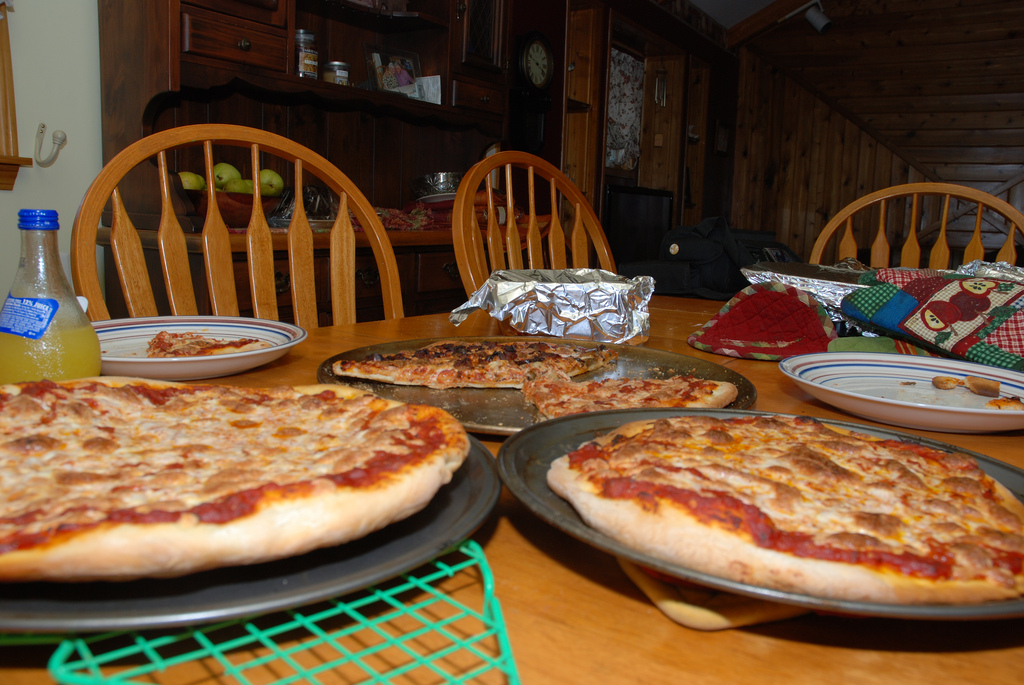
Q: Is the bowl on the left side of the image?
A: Yes, the bowl is on the left of the image.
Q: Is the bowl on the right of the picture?
A: No, the bowl is on the left of the image.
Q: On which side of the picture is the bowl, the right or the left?
A: The bowl is on the left of the image.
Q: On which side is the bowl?
A: The bowl is on the left of the image.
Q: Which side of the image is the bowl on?
A: The bowl is on the left of the image.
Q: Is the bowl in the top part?
A: Yes, the bowl is in the top of the image.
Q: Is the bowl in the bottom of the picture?
A: No, the bowl is in the top of the image.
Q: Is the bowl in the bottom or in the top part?
A: The bowl is in the top of the image.